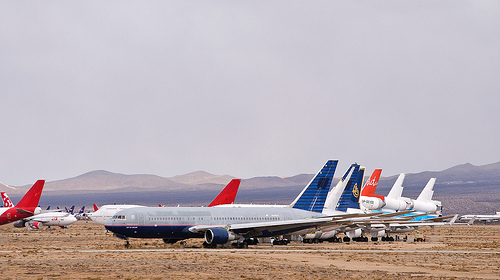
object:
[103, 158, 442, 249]
aircraft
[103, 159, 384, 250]
airplane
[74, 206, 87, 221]
airplane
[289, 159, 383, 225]
tail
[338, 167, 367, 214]
tail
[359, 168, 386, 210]
tail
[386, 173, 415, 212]
tail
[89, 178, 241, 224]
plane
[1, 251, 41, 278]
desert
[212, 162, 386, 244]
plane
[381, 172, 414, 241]
plane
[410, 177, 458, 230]
plane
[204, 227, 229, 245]
engine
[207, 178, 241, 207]
tail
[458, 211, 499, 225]
planes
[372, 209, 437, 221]
stripe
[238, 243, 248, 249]
wheels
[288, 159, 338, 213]
tail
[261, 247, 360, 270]
desert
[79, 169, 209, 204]
hills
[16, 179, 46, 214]
tail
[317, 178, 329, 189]
black square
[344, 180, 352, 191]
black square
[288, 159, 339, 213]
blue/blackstripes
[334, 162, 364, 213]
blue/blackstripes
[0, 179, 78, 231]
plane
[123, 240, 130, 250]
wheel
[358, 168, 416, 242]
plane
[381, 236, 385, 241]
wheel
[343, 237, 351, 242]
wheel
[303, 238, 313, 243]
wheel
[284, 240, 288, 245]
wheel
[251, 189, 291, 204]
ground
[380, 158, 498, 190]
mountain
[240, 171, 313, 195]
mountain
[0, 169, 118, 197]
mountain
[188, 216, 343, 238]
wings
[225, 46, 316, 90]
sky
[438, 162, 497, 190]
hills